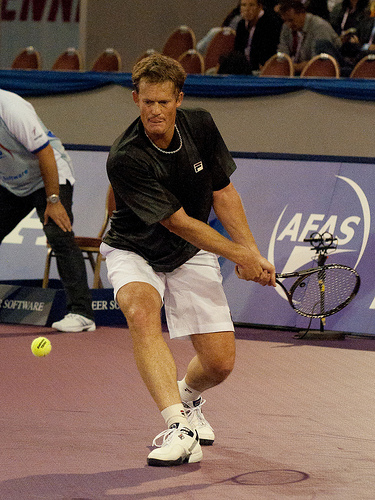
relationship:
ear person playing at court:
[98, 53, 273, 469] [0, 322, 373, 498]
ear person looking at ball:
[98, 53, 273, 469] [28, 334, 53, 355]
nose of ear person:
[151, 101, 161, 115] [98, 53, 273, 469]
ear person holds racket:
[98, 53, 273, 469] [257, 243, 360, 341]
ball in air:
[32, 334, 53, 357] [18, 321, 64, 370]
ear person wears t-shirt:
[98, 53, 273, 469] [102, 108, 237, 272]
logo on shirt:
[193, 160, 204, 176] [101, 107, 237, 272]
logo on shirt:
[268, 169, 369, 311] [0, 85, 77, 196]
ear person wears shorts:
[98, 53, 273, 469] [96, 234, 236, 339]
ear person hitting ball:
[98, 53, 273, 469] [29, 332, 56, 355]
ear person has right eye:
[98, 53, 273, 469] [142, 99, 154, 105]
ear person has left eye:
[98, 53, 273, 469] [154, 97, 174, 104]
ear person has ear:
[99, 53, 193, 131] [129, 88, 137, 107]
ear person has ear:
[98, 53, 273, 469] [174, 87, 183, 112]